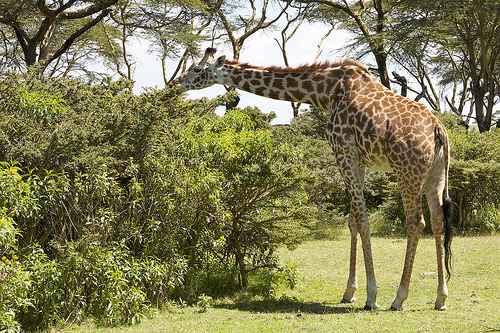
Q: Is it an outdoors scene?
A: Yes, it is outdoors.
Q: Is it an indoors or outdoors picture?
A: It is outdoors.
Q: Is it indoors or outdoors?
A: It is outdoors.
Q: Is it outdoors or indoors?
A: It is outdoors.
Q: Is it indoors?
A: No, it is outdoors.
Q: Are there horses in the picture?
A: No, there are no horses.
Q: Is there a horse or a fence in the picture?
A: No, there are no horses or fences.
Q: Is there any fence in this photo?
A: No, there are no fences.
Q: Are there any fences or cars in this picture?
A: No, there are no cars or fences.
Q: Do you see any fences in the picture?
A: No, there are no fences.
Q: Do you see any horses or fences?
A: No, there are no fences or horses.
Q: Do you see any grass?
A: Yes, there is grass.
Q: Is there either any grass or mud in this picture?
A: Yes, there is grass.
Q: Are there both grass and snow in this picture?
A: No, there is grass but no snow.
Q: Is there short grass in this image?
A: Yes, there is short grass.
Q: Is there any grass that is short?
A: Yes, there is grass that is short.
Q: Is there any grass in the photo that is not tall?
A: Yes, there is short grass.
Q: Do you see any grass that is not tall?
A: Yes, there is short grass.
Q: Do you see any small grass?
A: Yes, there is small grass.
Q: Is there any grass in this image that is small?
A: Yes, there is grass that is small.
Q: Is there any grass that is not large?
A: Yes, there is small grass.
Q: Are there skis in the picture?
A: No, there are no skis.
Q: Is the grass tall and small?
A: No, the grass is small but short.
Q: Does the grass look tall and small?
A: No, the grass is small but short.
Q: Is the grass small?
A: Yes, the grass is small.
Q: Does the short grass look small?
A: Yes, the grass is small.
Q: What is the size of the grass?
A: The grass is small.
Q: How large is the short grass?
A: The grass is small.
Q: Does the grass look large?
A: No, the grass is small.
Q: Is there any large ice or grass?
A: No, there is grass but it is small.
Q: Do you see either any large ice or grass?
A: No, there is grass but it is small.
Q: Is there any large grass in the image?
A: No, there is grass but it is small.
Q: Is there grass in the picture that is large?
A: No, there is grass but it is small.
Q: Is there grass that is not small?
A: No, there is grass but it is small.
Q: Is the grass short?
A: Yes, the grass is short.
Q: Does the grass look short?
A: Yes, the grass is short.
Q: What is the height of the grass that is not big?
A: The grass is short.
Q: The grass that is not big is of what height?
A: The grass is short.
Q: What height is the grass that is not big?
A: The grass is short.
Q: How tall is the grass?
A: The grass is short.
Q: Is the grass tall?
A: No, the grass is short.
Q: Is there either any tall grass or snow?
A: No, there is grass but it is short.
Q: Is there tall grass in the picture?
A: No, there is grass but it is short.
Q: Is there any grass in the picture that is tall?
A: No, there is grass but it is short.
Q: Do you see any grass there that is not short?
A: No, there is grass but it is short.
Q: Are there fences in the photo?
A: No, there are no fences.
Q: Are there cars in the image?
A: No, there are no cars.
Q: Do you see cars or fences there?
A: No, there are no cars or fences.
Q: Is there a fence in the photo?
A: No, there are no fences.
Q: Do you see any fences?
A: No, there are no fences.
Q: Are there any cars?
A: No, there are no cars.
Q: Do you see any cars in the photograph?
A: No, there are no cars.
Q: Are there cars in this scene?
A: No, there are no cars.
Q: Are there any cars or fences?
A: No, there are no cars or fences.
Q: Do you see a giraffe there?
A: Yes, there is a giraffe.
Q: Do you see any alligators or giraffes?
A: Yes, there is a giraffe.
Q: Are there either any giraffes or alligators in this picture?
A: Yes, there is a giraffe.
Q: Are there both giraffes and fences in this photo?
A: No, there is a giraffe but no fences.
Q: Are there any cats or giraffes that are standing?
A: Yes, the giraffe is standing.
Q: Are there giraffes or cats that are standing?
A: Yes, the giraffe is standing.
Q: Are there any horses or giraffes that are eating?
A: Yes, the giraffe is eating.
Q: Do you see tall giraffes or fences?
A: Yes, there is a tall giraffe.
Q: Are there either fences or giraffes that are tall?
A: Yes, the giraffe is tall.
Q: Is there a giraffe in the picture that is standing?
A: Yes, there is a giraffe that is standing.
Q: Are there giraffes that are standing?
A: Yes, there is a giraffe that is standing.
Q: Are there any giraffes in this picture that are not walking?
A: Yes, there is a giraffe that is standing.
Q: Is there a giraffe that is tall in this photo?
A: Yes, there is a tall giraffe.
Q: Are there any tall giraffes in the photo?
A: Yes, there is a tall giraffe.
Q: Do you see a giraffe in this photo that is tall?
A: Yes, there is a giraffe that is tall.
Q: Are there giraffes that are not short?
A: Yes, there is a tall giraffe.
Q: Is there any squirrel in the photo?
A: No, there are no squirrels.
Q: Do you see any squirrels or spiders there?
A: No, there are no squirrels or spiders.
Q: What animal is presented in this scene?
A: The animal is a giraffe.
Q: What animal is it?
A: The animal is a giraffe.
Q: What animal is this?
A: This is a giraffe.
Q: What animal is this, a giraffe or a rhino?
A: This is a giraffe.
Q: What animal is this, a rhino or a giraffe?
A: This is a giraffe.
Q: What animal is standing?
A: The animal is a giraffe.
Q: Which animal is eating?
A: The animal is a giraffe.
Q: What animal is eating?
A: The animal is a giraffe.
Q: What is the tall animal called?
A: The animal is a giraffe.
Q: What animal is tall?
A: The animal is a giraffe.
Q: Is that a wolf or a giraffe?
A: That is a giraffe.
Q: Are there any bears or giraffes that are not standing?
A: No, there is a giraffe but it is standing.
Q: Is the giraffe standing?
A: Yes, the giraffe is standing.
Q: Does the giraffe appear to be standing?
A: Yes, the giraffe is standing.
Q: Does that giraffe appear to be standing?
A: Yes, the giraffe is standing.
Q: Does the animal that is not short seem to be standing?
A: Yes, the giraffe is standing.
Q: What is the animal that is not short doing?
A: The giraffe is standing.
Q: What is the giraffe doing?
A: The giraffe is standing.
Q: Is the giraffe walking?
A: No, the giraffe is standing.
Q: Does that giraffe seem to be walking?
A: No, the giraffe is standing.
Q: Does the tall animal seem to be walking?
A: No, the giraffe is standing.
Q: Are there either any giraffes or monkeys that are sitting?
A: No, there is a giraffe but it is standing.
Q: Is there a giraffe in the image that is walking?
A: No, there is a giraffe but it is standing.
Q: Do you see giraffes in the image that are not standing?
A: No, there is a giraffe but it is standing.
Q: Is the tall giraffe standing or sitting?
A: The giraffe is standing.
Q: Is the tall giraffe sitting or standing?
A: The giraffe is standing.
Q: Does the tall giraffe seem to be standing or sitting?
A: The giraffe is standing.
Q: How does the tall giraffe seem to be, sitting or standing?
A: The giraffe is standing.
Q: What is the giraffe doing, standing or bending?
A: The giraffe is standing.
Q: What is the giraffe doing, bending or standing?
A: The giraffe is standing.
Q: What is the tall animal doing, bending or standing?
A: The giraffe is standing.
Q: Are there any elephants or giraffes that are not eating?
A: No, there is a giraffe but it is eating.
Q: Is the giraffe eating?
A: Yes, the giraffe is eating.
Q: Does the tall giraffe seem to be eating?
A: Yes, the giraffe is eating.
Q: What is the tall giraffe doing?
A: The giraffe is eating.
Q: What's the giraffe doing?
A: The giraffe is eating.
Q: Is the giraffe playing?
A: No, the giraffe is eating.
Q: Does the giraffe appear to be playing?
A: No, the giraffe is eating.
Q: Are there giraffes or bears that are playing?
A: No, there is a giraffe but it is eating.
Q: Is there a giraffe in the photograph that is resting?
A: No, there is a giraffe but it is eating.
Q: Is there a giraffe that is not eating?
A: No, there is a giraffe but it is eating.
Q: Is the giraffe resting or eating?
A: The giraffe is eating.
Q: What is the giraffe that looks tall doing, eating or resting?
A: The giraffe is eating.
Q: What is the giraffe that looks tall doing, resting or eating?
A: The giraffe is eating.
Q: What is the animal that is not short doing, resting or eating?
A: The giraffe is eating.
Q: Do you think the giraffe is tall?
A: Yes, the giraffe is tall.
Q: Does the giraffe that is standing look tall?
A: Yes, the giraffe is tall.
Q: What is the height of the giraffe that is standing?
A: The giraffe is tall.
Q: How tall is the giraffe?
A: The giraffe is tall.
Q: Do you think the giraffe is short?
A: No, the giraffe is tall.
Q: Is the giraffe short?
A: No, the giraffe is tall.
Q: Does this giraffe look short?
A: No, the giraffe is tall.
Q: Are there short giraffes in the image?
A: No, there is a giraffe but it is tall.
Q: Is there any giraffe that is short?
A: No, there is a giraffe but it is tall.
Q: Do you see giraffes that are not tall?
A: No, there is a giraffe but it is tall.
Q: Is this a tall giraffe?
A: Yes, this is a tall giraffe.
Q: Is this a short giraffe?
A: No, this is a tall giraffe.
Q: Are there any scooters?
A: No, there are no scooters.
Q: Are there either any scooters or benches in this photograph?
A: No, there are no scooters or benches.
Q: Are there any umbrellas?
A: No, there are no umbrellas.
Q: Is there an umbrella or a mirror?
A: No, there are no umbrellas or mirrors.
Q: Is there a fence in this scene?
A: No, there are no fences.